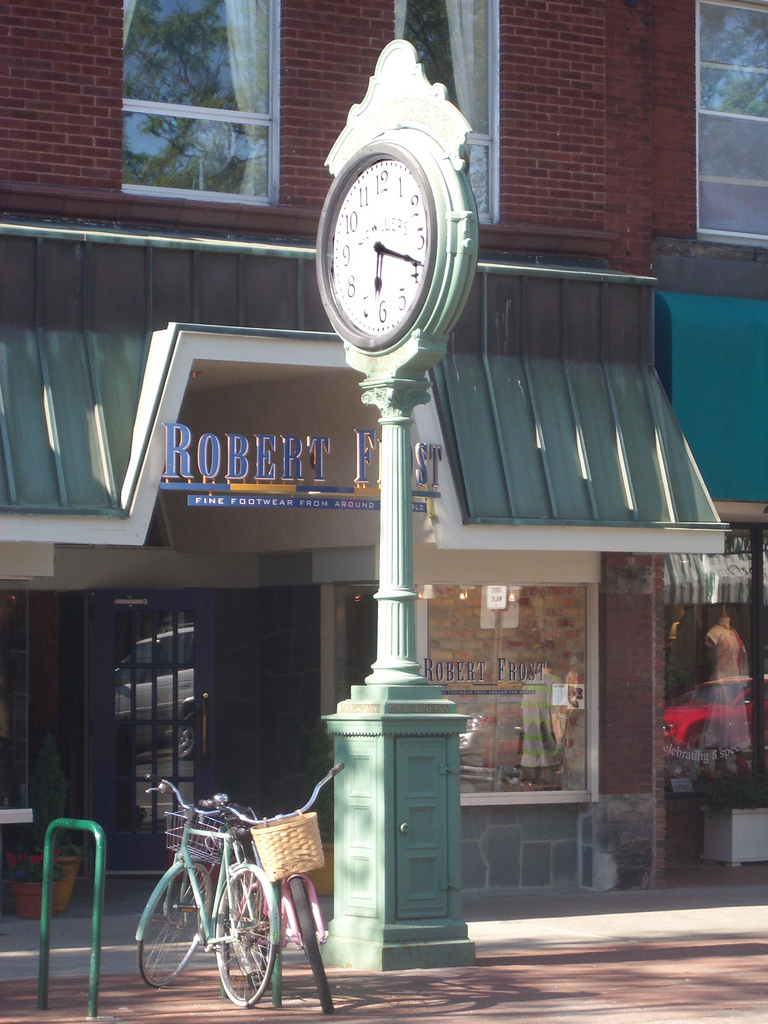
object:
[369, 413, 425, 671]
pole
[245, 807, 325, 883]
basket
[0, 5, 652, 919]
wall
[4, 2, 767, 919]
building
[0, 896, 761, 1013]
sidewalk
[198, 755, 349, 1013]
bicycle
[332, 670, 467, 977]
base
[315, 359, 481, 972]
pole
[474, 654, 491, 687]
lettering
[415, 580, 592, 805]
store window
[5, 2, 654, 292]
wall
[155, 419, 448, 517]
sign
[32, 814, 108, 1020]
barrier rail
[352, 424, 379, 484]
letters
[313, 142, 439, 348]
clock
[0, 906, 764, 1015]
street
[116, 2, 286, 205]
window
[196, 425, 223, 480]
o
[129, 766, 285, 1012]
bikes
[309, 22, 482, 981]
pole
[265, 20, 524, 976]
clock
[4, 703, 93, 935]
plants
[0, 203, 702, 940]
shop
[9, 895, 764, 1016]
ground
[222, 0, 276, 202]
curtains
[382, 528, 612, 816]
window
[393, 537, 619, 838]
window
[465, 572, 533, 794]
reflections